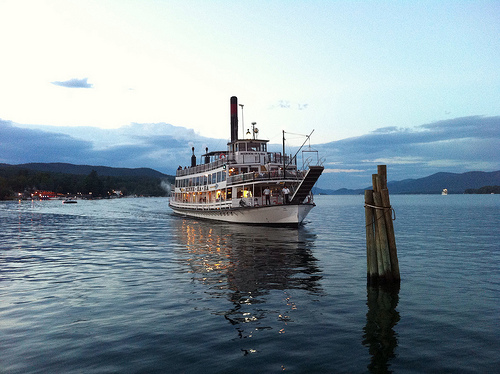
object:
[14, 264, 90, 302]
waters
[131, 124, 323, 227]
boat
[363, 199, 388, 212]
string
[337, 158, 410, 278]
post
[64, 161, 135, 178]
mountain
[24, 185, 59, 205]
houses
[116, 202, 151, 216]
shore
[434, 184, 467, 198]
object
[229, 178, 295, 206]
people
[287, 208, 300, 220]
light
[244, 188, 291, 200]
shirts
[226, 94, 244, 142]
stack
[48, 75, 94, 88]
clouds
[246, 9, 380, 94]
sky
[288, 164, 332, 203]
stairs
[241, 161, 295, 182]
crew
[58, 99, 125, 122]
sun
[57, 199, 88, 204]
station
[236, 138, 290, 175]
cabin